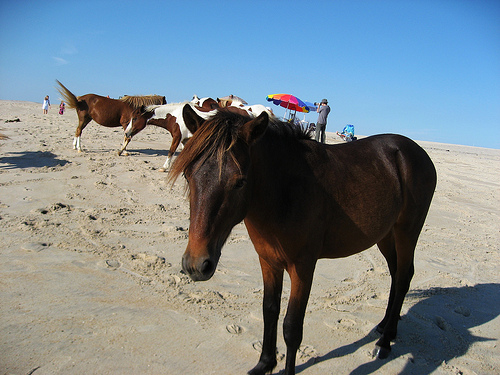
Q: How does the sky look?
A: Clear.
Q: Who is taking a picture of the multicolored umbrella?
A: Man with camera.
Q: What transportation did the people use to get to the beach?
A: Horse.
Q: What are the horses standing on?
A: Sand.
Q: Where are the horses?
A: On the sand.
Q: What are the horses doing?
A: Standing.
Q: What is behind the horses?
A: A person.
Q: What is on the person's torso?
A: A gray shirt.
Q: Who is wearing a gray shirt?
A: The person.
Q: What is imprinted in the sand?
A: Footprints.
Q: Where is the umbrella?
A: Behind the person.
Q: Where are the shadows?
A: Cast on the ground.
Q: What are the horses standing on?
A: Sand.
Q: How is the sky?
A: Clear.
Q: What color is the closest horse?
A: Brown.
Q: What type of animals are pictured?
A: Horses.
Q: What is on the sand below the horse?
A: Shadow.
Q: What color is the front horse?
A: Brown.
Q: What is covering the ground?
A: Sand.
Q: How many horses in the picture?
A: Five.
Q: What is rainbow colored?
A: The umbrella.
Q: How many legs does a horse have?
A: Four.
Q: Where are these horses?
A: On the beach.